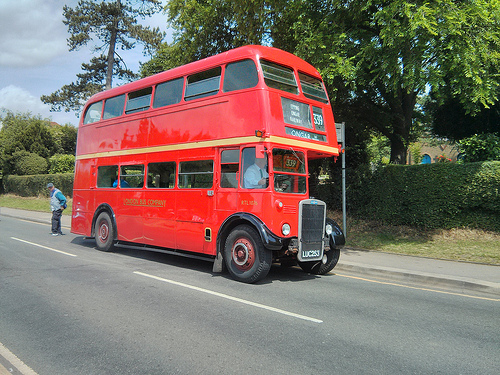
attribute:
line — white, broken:
[104, 252, 324, 364]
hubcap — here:
[226, 237, 264, 269]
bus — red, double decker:
[68, 63, 378, 276]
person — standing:
[42, 167, 73, 233]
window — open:
[178, 155, 219, 194]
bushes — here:
[365, 158, 481, 235]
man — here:
[34, 183, 68, 239]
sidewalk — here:
[338, 243, 478, 316]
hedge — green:
[346, 165, 496, 239]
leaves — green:
[426, 3, 499, 102]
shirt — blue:
[46, 194, 69, 213]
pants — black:
[42, 209, 66, 236]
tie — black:
[259, 163, 272, 188]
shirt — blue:
[114, 181, 127, 189]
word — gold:
[149, 190, 170, 214]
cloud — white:
[11, 21, 59, 97]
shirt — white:
[242, 161, 266, 188]